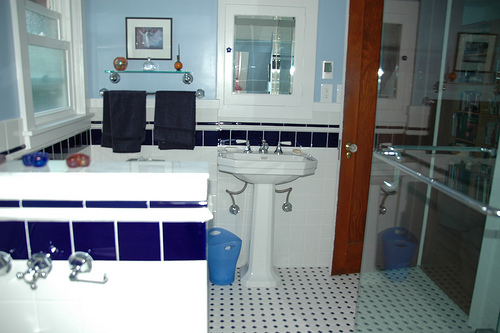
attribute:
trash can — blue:
[204, 224, 242, 286]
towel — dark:
[100, 89, 144, 154]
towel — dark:
[152, 89, 197, 149]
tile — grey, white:
[207, 264, 462, 329]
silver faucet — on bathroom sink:
[255, 137, 269, 157]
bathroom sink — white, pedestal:
[215, 134, 318, 289]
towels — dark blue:
[99, 87, 200, 155]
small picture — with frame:
[122, 10, 175, 63]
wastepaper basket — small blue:
[207, 224, 242, 284]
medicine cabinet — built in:
[215, 0, 321, 104]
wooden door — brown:
[328, 1, 381, 275]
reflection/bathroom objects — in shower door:
[385, 26, 474, 287]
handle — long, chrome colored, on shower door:
[371, 144, 484, 214]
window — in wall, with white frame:
[9, 3, 89, 134]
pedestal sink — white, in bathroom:
[214, 138, 318, 289]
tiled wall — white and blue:
[0, 176, 207, 331]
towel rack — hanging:
[100, 87, 205, 102]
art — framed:
[121, 12, 175, 64]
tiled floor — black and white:
[215, 289, 335, 331]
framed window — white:
[5, 3, 95, 151]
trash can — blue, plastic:
[206, 226, 244, 285]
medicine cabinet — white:
[214, 0, 319, 114]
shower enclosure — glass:
[379, 2, 484, 326]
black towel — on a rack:
[152, 90, 198, 153]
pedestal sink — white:
[216, 136, 480, 284]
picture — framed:
[123, 13, 175, 63]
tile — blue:
[5, 198, 204, 261]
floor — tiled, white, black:
[207, 267, 472, 331]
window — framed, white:
[10, 0, 89, 150]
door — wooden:
[332, 3, 384, 276]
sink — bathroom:
[217, 137, 314, 288]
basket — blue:
[209, 225, 241, 284]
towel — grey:
[106, 92, 146, 149]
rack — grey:
[96, 88, 209, 98]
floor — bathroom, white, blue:
[212, 262, 463, 330]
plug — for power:
[316, 84, 336, 103]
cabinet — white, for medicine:
[215, 5, 316, 125]